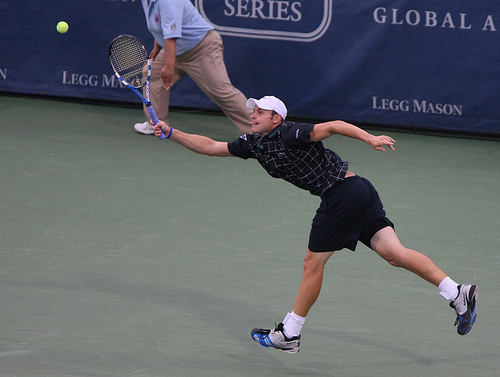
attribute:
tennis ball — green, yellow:
[57, 21, 69, 35]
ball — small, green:
[56, 19, 70, 34]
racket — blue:
[105, 33, 167, 140]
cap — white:
[244, 94, 295, 128]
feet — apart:
[246, 317, 301, 356]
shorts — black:
[308, 171, 399, 256]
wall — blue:
[300, 23, 493, 117]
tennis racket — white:
[106, 31, 167, 145]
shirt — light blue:
[140, 2, 212, 51]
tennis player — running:
[144, 89, 484, 352]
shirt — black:
[224, 130, 353, 196]